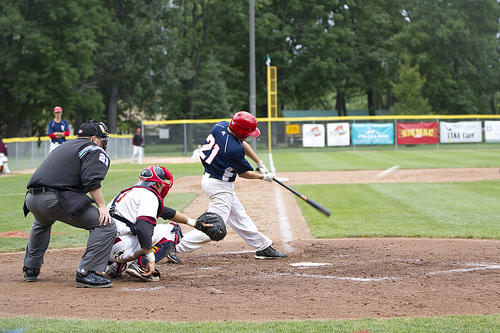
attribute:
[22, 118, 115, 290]
umpire — crouching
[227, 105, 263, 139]
helmet — red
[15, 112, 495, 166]
fence — metal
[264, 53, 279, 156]
foul pole — yellow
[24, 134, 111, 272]
uniform — black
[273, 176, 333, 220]
bat — black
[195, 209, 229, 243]
catcher's mitt — black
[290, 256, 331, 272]
home plate — white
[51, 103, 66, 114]
baseball hat — red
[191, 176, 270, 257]
pants — white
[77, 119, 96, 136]
hat — black